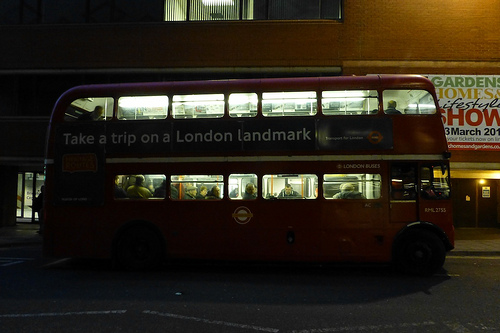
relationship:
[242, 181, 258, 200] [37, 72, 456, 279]
person riding on bus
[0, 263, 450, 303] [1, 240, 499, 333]
shadow on top of road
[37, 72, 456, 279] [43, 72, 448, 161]
bus has top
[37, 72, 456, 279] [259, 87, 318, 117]
bus has window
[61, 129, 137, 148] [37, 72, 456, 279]
letters on side of bus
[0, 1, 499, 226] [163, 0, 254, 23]
building has window shades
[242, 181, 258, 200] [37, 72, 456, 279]
person sitting inside bus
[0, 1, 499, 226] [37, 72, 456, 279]
building behind bus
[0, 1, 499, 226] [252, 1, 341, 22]
building has window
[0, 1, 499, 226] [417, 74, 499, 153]
building has sign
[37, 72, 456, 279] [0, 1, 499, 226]
bus in front of building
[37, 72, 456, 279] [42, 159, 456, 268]
bus has first level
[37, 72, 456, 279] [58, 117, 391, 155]
bus has sign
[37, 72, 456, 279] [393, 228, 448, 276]
bus has front wheel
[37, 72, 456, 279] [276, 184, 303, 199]
bus has passenger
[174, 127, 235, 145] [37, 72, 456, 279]
word on side of bus